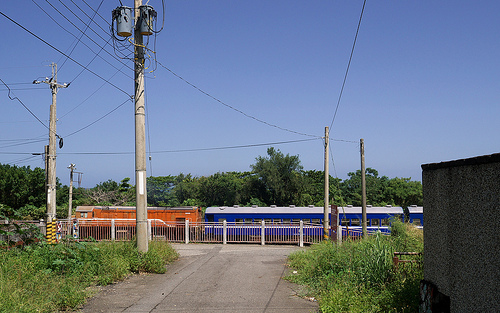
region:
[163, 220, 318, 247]
a white long fence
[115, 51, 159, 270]
electric pole is gray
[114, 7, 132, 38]
More visible transformer bucket on a pole.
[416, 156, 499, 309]
The side of a speckled grey and black concrete building.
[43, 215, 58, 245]
Two yellow and black wrapped bottom of poles.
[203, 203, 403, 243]
The longest visible blue and white train car.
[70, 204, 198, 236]
Orange train car.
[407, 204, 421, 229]
Blue and white train car that is barely visible.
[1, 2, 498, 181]
A blue sky.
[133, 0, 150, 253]
A grey pole with two transformer buckets on it.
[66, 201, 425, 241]
An orange and blue train.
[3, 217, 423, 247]
A long white and grey fence.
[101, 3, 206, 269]
here is a post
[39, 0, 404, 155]
these are power lines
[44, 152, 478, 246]
here is a train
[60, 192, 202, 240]
this is an orange train car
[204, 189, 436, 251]
these train cars are blue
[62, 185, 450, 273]
this is a passenger train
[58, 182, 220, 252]
the train engine is orange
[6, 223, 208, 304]
these are green plants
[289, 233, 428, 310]
green brush on the side of the road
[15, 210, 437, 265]
the fence has white posts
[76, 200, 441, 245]
train on the tracks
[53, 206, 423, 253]
white fence alongside the train tracks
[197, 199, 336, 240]
blue and gray train car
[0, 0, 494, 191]
blue sky with nos visible clouds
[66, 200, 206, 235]
front car is burnt orange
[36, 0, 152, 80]
five wires running parallel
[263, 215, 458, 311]
overgrown grass on the ground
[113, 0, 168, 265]
pole sticking out of the gras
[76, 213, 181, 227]
white stripe on the train car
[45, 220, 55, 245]
black and yellow stripes